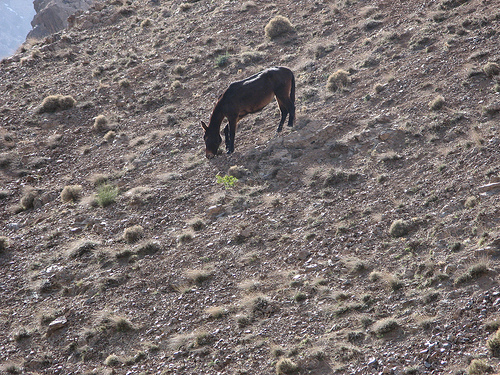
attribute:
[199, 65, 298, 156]
donkey — standing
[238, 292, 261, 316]
grass — brown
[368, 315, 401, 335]
grass — brown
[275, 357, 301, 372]
grass — brown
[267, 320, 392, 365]
grass — brown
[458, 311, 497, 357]
grass — brown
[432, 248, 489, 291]
grass — brown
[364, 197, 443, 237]
grass — brown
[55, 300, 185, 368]
grass — brown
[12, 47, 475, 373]
scene — outdoors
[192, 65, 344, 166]
donkey — black, grazing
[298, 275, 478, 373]
ground — desert, rocky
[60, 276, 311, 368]
ground — rocky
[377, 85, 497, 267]
ground — rocky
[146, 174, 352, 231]
ground — rocky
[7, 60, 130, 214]
ground — rocky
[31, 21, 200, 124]
ground — rocky